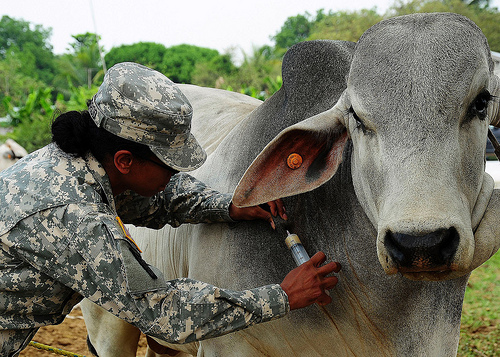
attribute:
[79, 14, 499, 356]
cow — gray, grey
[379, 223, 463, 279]
nose — big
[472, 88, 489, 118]
eye — black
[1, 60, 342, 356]
woman — camouflage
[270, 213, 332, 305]
needle — large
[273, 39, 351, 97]
hump — gray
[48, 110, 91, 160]
ponytail — black